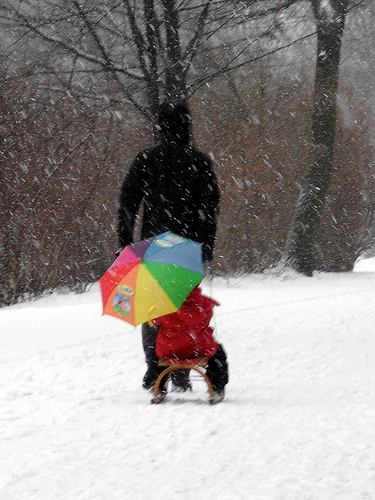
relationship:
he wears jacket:
[109, 88, 227, 268] [109, 91, 226, 258]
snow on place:
[253, 363, 359, 488] [229, 337, 372, 499]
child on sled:
[142, 283, 229, 399] [144, 356, 224, 405]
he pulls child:
[115, 91, 231, 398] [137, 287, 234, 406]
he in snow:
[115, 91, 231, 398] [268, 324, 344, 428]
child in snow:
[142, 283, 229, 399] [268, 324, 344, 428]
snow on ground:
[0, 254, 375, 500] [189, 420, 325, 481]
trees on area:
[87, 40, 244, 102] [227, 251, 372, 329]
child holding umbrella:
[137, 287, 234, 406] [98, 228, 206, 322]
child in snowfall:
[137, 287, 234, 406] [219, 144, 292, 281]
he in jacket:
[115, 91, 231, 398] [116, 149, 220, 235]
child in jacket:
[137, 287, 234, 406] [161, 313, 217, 355]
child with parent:
[142, 283, 229, 399] [108, 86, 219, 231]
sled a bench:
[148, 363, 224, 404] [159, 356, 205, 366]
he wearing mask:
[115, 91, 231, 398] [158, 112, 191, 152]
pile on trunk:
[259, 260, 311, 283] [259, 1, 350, 277]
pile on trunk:
[309, 267, 337, 278] [259, 1, 350, 277]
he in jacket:
[115, 91, 231, 398] [115, 145, 221, 258]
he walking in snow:
[115, 91, 231, 398] [1, 249, 373, 497]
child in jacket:
[142, 283, 229, 399] [151, 284, 219, 359]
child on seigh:
[142, 283, 229, 399] [150, 353, 227, 404]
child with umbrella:
[142, 283, 229, 399] [98, 231, 209, 327]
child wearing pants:
[142, 283, 229, 399] [207, 344, 228, 393]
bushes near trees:
[2, 57, 371, 304] [5, 0, 243, 102]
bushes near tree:
[2, 57, 371, 304] [260, 2, 373, 279]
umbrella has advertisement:
[98, 228, 206, 322] [155, 230, 188, 249]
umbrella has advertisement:
[98, 228, 206, 322] [113, 282, 134, 317]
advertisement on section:
[113, 284, 136, 318] [104, 261, 141, 325]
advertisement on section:
[155, 229, 186, 250] [142, 227, 203, 258]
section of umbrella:
[104, 261, 141, 325] [98, 228, 206, 322]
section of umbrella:
[142, 227, 203, 258] [98, 228, 206, 322]